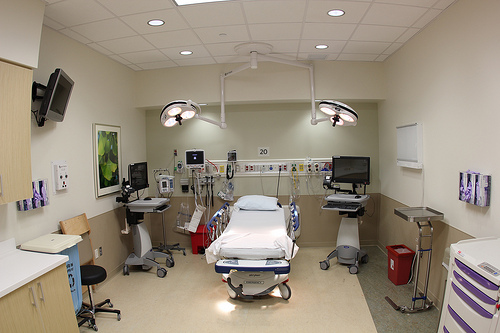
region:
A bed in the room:
[215, 180, 290, 279]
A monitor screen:
[330, 146, 376, 196]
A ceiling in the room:
[259, 11, 309, 58]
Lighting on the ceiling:
[327, 9, 350, 23]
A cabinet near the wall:
[14, 250, 76, 331]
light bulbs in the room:
[160, 94, 219, 139]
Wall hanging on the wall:
[92, 122, 121, 199]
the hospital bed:
[204, 194, 300, 301]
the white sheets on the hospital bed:
[203, 194, 300, 300]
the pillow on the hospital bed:
[203, 193, 300, 300]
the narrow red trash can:
[385, 241, 415, 286]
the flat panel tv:
[31, 67, 74, 127]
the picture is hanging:
[91, 121, 123, 198]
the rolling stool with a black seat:
[79, 265, 121, 330]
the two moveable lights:
[159, 42, 359, 127]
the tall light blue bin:
[18, 233, 83, 318]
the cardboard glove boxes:
[457, 170, 491, 205]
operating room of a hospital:
[3, 10, 495, 328]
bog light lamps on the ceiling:
[146, 37, 368, 137]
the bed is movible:
[188, 184, 307, 301]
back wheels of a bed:
[213, 269, 298, 303]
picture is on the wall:
[89, 115, 129, 200]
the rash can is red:
[379, 239, 420, 288]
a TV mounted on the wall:
[33, 56, 80, 129]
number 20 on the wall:
[251, 138, 278, 161]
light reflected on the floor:
[204, 281, 242, 321]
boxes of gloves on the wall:
[450, 157, 497, 214]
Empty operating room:
[53, 20, 489, 330]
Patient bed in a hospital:
[207, 190, 301, 300]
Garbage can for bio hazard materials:
[384, 242, 419, 287]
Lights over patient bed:
[159, 45, 361, 127]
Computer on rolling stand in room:
[318, 153, 371, 276]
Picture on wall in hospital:
[90, 122, 125, 198]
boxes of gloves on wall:
[455, 170, 489, 207]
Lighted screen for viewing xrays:
[391, 124, 423, 173]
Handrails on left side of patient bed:
[207, 205, 227, 240]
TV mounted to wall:
[34, 67, 76, 128]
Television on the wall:
[34, 64, 76, 130]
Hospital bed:
[205, 195, 305, 304]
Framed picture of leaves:
[86, 120, 129, 200]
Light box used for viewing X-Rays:
[394, 123, 428, 174]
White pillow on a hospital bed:
[232, 192, 282, 213]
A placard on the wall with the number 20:
[256, 145, 271, 158]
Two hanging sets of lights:
[154, 97, 364, 130]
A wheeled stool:
[67, 260, 132, 330]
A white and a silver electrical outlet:
[88, 245, 110, 258]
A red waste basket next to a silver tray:
[377, 236, 422, 288]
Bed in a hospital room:
[203, 182, 316, 317]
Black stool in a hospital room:
[71, 261, 121, 322]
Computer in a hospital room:
[321, 153, 376, 217]